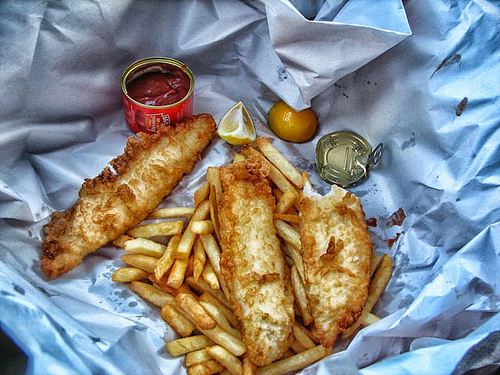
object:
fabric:
[0, 0, 494, 373]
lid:
[314, 129, 386, 188]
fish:
[298, 172, 371, 348]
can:
[120, 57, 195, 135]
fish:
[219, 160, 295, 367]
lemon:
[217, 100, 258, 146]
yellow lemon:
[268, 97, 318, 143]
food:
[39, 57, 391, 374]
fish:
[41, 113, 218, 278]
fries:
[197, 234, 229, 303]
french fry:
[258, 137, 304, 188]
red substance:
[128, 72, 190, 107]